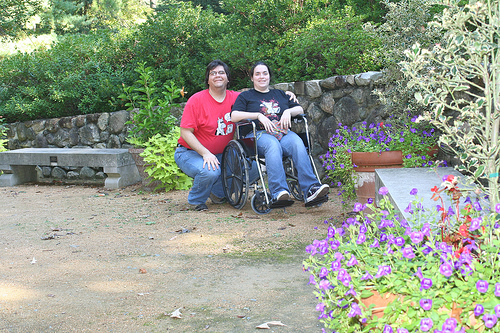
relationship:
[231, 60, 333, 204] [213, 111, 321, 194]
people in wheelchair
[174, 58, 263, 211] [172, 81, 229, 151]
man wearing shirt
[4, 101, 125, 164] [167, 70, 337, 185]
wall behind women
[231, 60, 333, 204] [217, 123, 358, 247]
people in wheelchair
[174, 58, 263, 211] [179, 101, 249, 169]
man with shirt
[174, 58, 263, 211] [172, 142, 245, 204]
man with blue jeans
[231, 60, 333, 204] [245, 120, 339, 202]
people with jeans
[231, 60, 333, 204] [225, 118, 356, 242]
people with wheelchair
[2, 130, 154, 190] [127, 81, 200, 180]
bench with plant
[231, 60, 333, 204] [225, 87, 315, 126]
people with shirt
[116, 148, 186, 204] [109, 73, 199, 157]
pot with plants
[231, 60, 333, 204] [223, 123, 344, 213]
people with wheelchair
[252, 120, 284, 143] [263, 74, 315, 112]
hand with shouler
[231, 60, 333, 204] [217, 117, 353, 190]
people with wheelchair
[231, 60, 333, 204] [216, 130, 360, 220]
people with wheelchair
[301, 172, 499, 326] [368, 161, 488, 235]
flowers near bench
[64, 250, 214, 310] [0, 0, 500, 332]
dirt in backyard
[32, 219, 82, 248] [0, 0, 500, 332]
gravel in backyard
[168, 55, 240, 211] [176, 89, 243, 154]
man wears shirt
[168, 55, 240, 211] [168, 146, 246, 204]
man wears blue jeans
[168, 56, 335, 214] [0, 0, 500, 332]
friends in backyard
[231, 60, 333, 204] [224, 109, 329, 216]
people in wheelchair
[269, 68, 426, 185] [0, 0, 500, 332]
wall in backyard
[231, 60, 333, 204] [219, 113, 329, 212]
people squatting down beside wheel chair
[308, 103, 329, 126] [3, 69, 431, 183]
stone in wall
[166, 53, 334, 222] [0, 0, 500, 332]
people are in backyard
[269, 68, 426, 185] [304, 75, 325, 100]
wall has stone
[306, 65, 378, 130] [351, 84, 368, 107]
wall has stone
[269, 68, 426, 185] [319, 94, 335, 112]
wall has stone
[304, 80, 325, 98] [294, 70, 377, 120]
stone in wall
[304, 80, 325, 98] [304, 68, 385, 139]
stone in wall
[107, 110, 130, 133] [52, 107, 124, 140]
stone in wall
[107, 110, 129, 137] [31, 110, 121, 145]
stone in wall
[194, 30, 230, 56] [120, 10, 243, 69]
leaves on tree